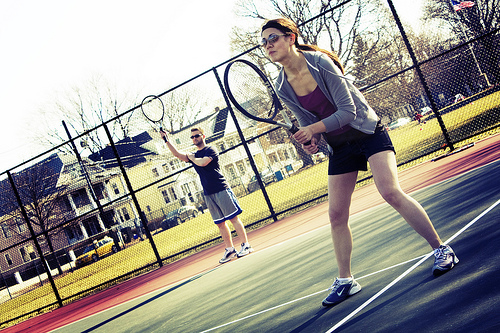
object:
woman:
[220, 13, 465, 316]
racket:
[221, 55, 319, 156]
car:
[72, 234, 121, 267]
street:
[0, 256, 90, 304]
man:
[156, 126, 255, 264]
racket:
[138, 94, 172, 145]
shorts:
[320, 122, 399, 177]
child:
[406, 108, 433, 127]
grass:
[395, 124, 425, 147]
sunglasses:
[188, 132, 204, 143]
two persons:
[132, 10, 468, 315]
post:
[442, 0, 494, 88]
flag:
[440, 0, 476, 17]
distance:
[0, 153, 124, 333]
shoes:
[317, 272, 369, 309]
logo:
[331, 285, 351, 299]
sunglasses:
[259, 32, 291, 48]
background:
[356, 0, 499, 83]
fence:
[0, 2, 499, 329]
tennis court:
[0, 137, 500, 333]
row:
[42, 141, 195, 241]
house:
[0, 149, 147, 289]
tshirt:
[183, 146, 231, 198]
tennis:
[215, 54, 342, 160]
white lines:
[326, 200, 500, 332]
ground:
[25, 153, 499, 333]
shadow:
[429, 160, 498, 225]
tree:
[301, 2, 403, 42]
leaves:
[364, 29, 373, 37]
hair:
[257, 17, 346, 68]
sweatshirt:
[270, 50, 384, 159]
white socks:
[336, 272, 357, 286]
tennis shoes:
[410, 242, 463, 288]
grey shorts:
[201, 189, 244, 224]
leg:
[367, 144, 444, 253]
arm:
[288, 56, 358, 147]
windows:
[2, 252, 15, 266]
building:
[0, 149, 136, 273]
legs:
[314, 162, 361, 309]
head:
[254, 12, 298, 66]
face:
[258, 27, 293, 60]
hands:
[289, 120, 322, 146]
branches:
[321, 0, 346, 56]